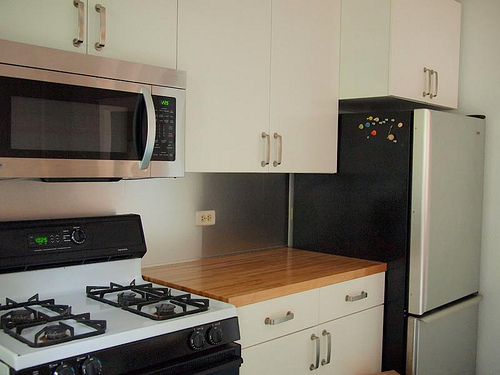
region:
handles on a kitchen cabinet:
[241, 119, 311, 179]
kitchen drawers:
[228, 275, 418, 347]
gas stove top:
[1, 268, 264, 368]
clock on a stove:
[7, 207, 133, 276]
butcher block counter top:
[153, 235, 415, 319]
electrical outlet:
[178, 192, 246, 257]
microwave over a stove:
[3, 32, 265, 372]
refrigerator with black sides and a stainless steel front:
[280, 103, 481, 368]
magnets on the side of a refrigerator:
[350, 100, 406, 156]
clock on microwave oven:
[140, 82, 192, 123]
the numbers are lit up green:
[157, 96, 174, 107]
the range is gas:
[0, 278, 196, 328]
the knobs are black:
[181, 320, 227, 356]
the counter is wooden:
[205, 250, 351, 266]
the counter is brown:
[210, 242, 383, 294]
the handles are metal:
[310, 330, 335, 370]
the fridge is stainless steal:
[406, 100, 494, 373]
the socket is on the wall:
[188, 206, 218, 228]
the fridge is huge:
[400, 101, 497, 371]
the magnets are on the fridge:
[350, 112, 405, 145]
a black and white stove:
[0, 213, 245, 374]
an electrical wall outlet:
[194, 209, 217, 226]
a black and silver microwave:
[0, 39, 185, 179]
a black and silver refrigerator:
[287, 106, 486, 373]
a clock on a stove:
[30, 234, 50, 244]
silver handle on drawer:
[262, 310, 295, 326]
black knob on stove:
[207, 324, 224, 346]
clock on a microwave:
[155, 96, 174, 108]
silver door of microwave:
[0, 60, 156, 177]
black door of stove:
[123, 339, 246, 374]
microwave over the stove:
[0, 29, 206, 196]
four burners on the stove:
[9, 261, 234, 338]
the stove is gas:
[8, 305, 89, 347]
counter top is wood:
[199, 239, 331, 279]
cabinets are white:
[237, 27, 319, 109]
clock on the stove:
[20, 228, 68, 250]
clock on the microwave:
[155, 96, 185, 107]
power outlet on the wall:
[189, 207, 238, 229]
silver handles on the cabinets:
[261, 121, 288, 165]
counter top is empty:
[168, 227, 347, 276]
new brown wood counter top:
[196, 251, 303, 282]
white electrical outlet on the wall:
[174, 200, 236, 236]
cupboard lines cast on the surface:
[188, 131, 275, 271]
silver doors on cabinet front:
[295, 323, 339, 368]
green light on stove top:
[18, 219, 80, 255]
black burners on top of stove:
[93, 269, 204, 326]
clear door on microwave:
[10, 68, 165, 170]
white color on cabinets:
[195, 6, 327, 91]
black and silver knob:
[64, 216, 114, 246]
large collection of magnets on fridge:
[345, 103, 431, 170]